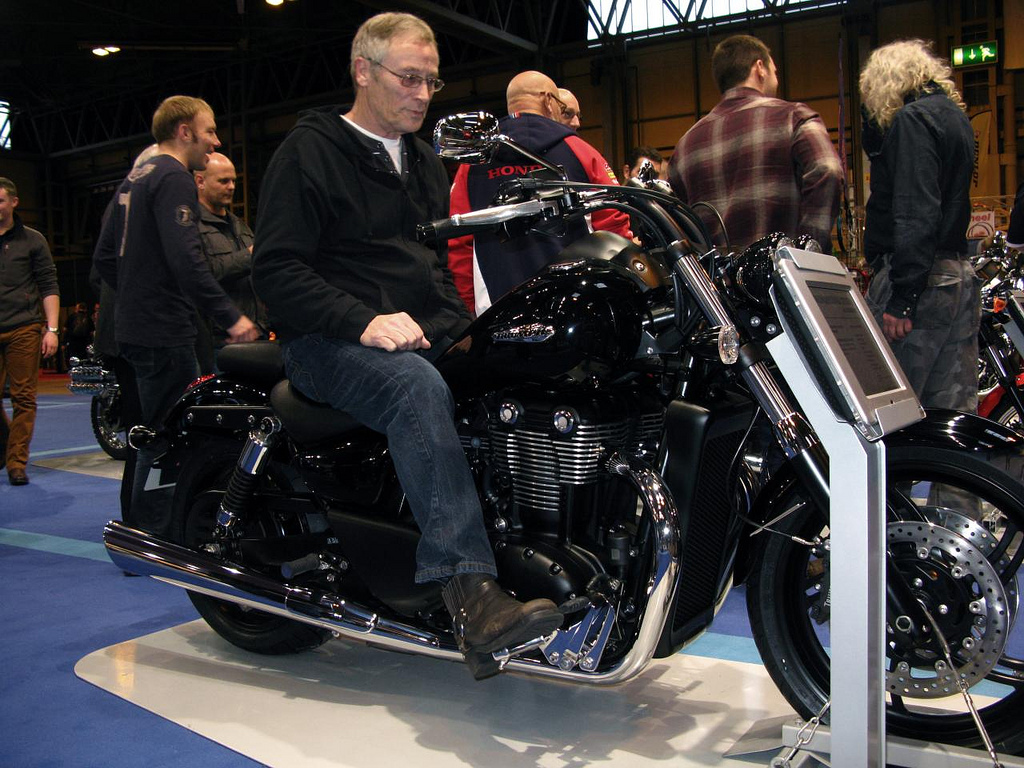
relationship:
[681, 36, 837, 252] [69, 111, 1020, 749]
man standing bike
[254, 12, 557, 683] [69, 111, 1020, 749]
man standing bike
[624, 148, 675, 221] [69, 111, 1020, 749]
person beside bike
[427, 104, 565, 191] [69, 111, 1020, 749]
rear mirror on bike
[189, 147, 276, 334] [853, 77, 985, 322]
man wearing black shirt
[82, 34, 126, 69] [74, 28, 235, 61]
light on beam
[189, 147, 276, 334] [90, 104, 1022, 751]
man on bike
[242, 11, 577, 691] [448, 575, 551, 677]
man wearing boots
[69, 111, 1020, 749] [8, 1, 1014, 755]
bike in room